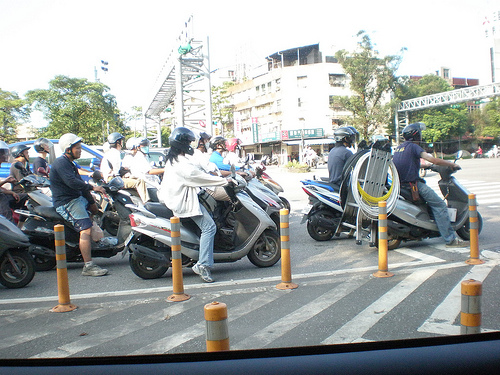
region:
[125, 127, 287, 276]
a woman on a motorcycle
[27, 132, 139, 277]
a man on a motorcycle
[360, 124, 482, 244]
a man on a motorcycle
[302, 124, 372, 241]
a man on a motorcycle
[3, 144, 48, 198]
a man on a motorcycle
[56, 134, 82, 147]
a protective motorcycle helmet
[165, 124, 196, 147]
a protective motorcycle helmet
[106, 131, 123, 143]
a protective motorcycle helmet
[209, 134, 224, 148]
a protective motorcycle helmet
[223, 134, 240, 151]
a protective motorcycle helmet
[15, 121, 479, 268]
Group of motorcyclists stopped at a street intersection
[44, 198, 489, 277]
Orange and silver barrier poles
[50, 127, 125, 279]
Man wearing a blue sweatshirt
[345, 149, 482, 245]
Motorcycle towing a ladder and cables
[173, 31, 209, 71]
Blue rag hanging on metal structure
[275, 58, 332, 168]
Corner building with red and blue sign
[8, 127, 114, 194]
Blue automobile behind bikers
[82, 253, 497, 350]
White zig zag lines on street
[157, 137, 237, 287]
Motorcyclist wearing a white jacket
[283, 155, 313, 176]
Small green bush in center of road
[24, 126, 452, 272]
Many people riding scooters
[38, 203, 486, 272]
Orange poles with white stripes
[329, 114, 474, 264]
Ladders on back of scooter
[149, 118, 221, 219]
Woman wearing a black helmet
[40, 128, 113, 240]
Man sitting on a scooter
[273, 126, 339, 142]
Green and red sign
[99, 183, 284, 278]
The scooter is grey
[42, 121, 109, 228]
The man is wearing a black sweatshirt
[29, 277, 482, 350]
White lines on the asphalt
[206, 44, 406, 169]
The building has many floors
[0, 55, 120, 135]
a back round of trees.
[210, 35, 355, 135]
a corner of buildings.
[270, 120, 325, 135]
a store sign is on the building.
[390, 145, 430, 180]
a man is wearing a blue tea shirt.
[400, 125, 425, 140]
a biker is wearing a black helmet.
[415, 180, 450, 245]
a biker is wearing jeans.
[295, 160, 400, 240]
the two motorcycles are red white and blue.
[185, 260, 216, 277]
a woman is wearing grey and white sneakers.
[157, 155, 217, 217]
a woman is wearing a white jacket.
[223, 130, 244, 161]
a woman is wearing a pink helmet.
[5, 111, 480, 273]
a group of people on scooters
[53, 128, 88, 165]
white helmet with a thick black strap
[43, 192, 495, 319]
row of pylons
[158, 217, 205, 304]
yellow and white pylon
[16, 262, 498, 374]
diagonal white lines painted on the ground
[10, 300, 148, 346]
spot where the white paint is fading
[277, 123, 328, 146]
sign on the building on the corner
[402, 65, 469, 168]
thick green tree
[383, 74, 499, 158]
metal structure that hangs over the street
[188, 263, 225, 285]
toe touching the ground